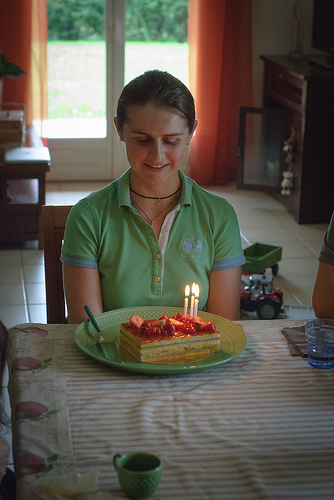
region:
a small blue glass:
[302, 317, 333, 368]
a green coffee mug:
[107, 449, 166, 498]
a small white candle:
[182, 295, 188, 315]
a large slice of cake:
[120, 312, 218, 359]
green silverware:
[80, 302, 108, 343]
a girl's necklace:
[131, 200, 176, 231]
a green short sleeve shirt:
[61, 168, 244, 310]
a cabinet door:
[235, 102, 287, 192]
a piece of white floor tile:
[236, 214, 285, 230]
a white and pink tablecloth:
[12, 316, 332, 497]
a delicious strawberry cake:
[123, 313, 224, 361]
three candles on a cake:
[179, 279, 204, 338]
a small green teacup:
[109, 444, 169, 497]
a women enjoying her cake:
[84, 65, 225, 370]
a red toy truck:
[241, 264, 291, 322]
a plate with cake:
[71, 299, 247, 375]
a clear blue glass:
[299, 311, 333, 374]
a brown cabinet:
[249, 42, 330, 227]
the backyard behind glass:
[40, 4, 119, 181]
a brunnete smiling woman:
[120, 66, 197, 188]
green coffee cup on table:
[93, 452, 181, 497]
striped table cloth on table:
[5, 394, 265, 460]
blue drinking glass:
[302, 312, 332, 378]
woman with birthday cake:
[45, 71, 245, 392]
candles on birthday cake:
[174, 276, 204, 321]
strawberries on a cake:
[121, 314, 221, 369]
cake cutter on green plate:
[79, 306, 122, 376]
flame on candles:
[179, 276, 200, 297]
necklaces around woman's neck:
[122, 183, 187, 233]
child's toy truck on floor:
[228, 254, 290, 330]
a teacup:
[108, 434, 148, 479]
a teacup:
[95, 425, 161, 490]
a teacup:
[146, 454, 166, 483]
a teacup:
[131, 423, 174, 483]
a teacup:
[84, 423, 130, 471]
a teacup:
[122, 446, 178, 495]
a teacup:
[123, 434, 160, 484]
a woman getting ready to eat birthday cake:
[59, 63, 260, 408]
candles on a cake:
[169, 270, 223, 363]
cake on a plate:
[65, 265, 274, 397]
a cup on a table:
[81, 439, 179, 498]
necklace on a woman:
[115, 173, 206, 238]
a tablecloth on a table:
[11, 301, 330, 489]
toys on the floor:
[226, 235, 293, 342]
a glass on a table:
[293, 300, 331, 383]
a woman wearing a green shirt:
[43, 65, 259, 336]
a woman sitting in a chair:
[36, 52, 247, 365]